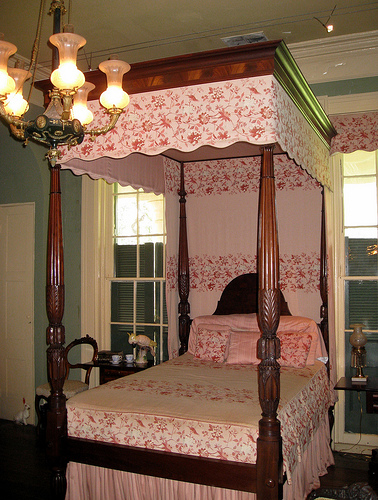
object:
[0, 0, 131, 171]
chandelier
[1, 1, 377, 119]
ceiling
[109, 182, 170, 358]
window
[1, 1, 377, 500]
room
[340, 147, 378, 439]
window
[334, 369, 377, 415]
table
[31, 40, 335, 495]
bed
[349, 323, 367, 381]
lamp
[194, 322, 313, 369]
pillows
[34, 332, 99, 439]
chair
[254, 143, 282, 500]
post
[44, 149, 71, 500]
post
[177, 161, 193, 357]
post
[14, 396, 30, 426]
door stop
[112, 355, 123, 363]
teacup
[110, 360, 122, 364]
saucer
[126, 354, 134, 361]
teacup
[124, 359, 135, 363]
saucer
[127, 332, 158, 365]
bird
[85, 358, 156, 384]
table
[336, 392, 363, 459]
cord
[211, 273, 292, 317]
headboard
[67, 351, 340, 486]
bedspread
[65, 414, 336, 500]
bed skirt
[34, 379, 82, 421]
seat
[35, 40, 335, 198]
canopy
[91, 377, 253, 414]
flowers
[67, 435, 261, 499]
footboard